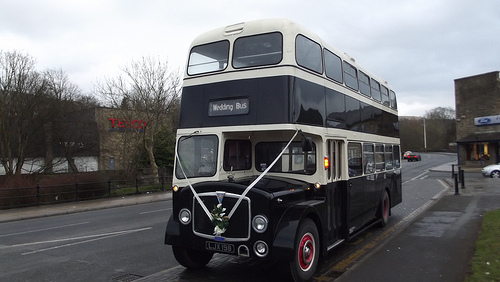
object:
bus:
[165, 17, 403, 282]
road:
[1, 151, 450, 279]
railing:
[0, 165, 166, 212]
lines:
[302, 177, 450, 282]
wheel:
[278, 216, 321, 282]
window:
[232, 31, 281, 69]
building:
[454, 70, 500, 166]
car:
[481, 162, 499, 179]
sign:
[107, 116, 146, 129]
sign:
[474, 115, 500, 125]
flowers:
[211, 222, 229, 237]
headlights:
[179, 209, 189, 225]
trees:
[0, 50, 98, 187]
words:
[212, 102, 247, 112]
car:
[406, 152, 422, 162]